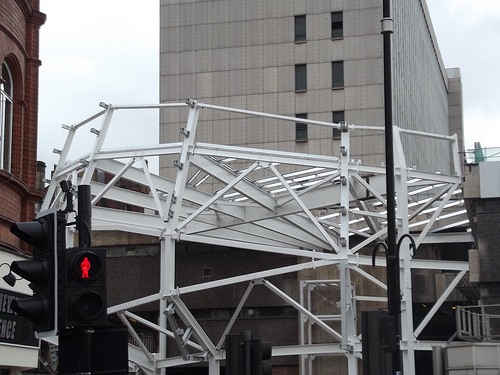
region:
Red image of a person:
[62, 248, 112, 295]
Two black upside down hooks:
[366, 221, 438, 290]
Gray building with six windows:
[158, 0, 471, 227]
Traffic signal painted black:
[6, 207, 65, 339]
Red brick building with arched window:
[5, 1, 44, 298]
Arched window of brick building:
[0, 46, 29, 184]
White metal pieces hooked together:
[51, 114, 456, 343]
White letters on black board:
[3, 297, 23, 349]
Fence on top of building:
[467, 145, 499, 162]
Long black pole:
[377, 6, 421, 373]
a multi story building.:
[157, 0, 457, 239]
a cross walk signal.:
[60, 241, 143, 335]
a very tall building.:
[153, 0, 461, 182]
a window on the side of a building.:
[326, 1, 348, 39]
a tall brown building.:
[3, 0, 57, 257]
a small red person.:
[80, 253, 97, 283]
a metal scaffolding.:
[40, 88, 485, 270]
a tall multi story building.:
[154, 0, 466, 203]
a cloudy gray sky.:
[38, 0, 165, 177]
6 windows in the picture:
[280, 6, 358, 157]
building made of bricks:
[1, 134, 46, 237]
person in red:
[48, 241, 127, 307]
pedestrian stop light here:
[46, 230, 129, 343]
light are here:
[420, 289, 476, 327]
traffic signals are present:
[4, 203, 129, 359]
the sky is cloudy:
[58, 33, 104, 86]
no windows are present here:
[172, 31, 267, 121]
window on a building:
[3, 49, 30, 196]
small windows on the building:
[195, 254, 241, 328]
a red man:
[78, 255, 93, 276]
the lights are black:
[17, 215, 129, 372]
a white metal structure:
[41, 100, 492, 370]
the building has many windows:
[160, 0, 467, 196]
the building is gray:
[158, 0, 458, 227]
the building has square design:
[159, 0, 466, 183]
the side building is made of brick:
[0, 0, 45, 258]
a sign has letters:
[0, 292, 18, 344]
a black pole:
[384, 0, 400, 372]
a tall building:
[160, 1, 465, 226]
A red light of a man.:
[73, 256, 95, 276]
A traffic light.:
[12, 173, 136, 373]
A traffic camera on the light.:
[55, 173, 79, 218]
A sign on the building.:
[465, 142, 488, 164]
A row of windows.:
[278, 4, 350, 144]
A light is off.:
[69, 282, 107, 324]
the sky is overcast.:
[63, 10, 143, 91]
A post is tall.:
[353, 1, 416, 372]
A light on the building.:
[0, 259, 24, 291]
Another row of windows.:
[92, 241, 159, 262]